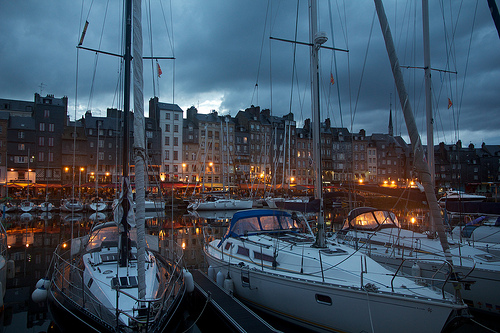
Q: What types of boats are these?
A: Sailboats.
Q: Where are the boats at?
A: Docked.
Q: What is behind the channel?
A: Buildings.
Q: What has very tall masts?
A: The boats.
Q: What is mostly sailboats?
A: The boats.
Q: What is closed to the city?
A: The boats.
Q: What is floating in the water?
A: The boats.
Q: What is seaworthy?
A: The boats.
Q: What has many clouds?
A: The sky.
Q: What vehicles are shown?
A: Boats.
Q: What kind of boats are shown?
A: Sail boats.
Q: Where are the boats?
A: At a dock.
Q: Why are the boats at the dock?
A: To park.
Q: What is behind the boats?
A: Buildings.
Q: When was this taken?
A: Dusk.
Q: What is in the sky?
A: Clouds.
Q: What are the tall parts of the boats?
A: Masts.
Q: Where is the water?
A: In the ocean.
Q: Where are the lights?
A: In front of buildings.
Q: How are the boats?
A: Rows.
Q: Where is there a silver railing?
A: Around a boat.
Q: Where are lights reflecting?
A: In the water.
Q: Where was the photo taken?
A: A marina.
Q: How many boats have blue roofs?
A: 1.